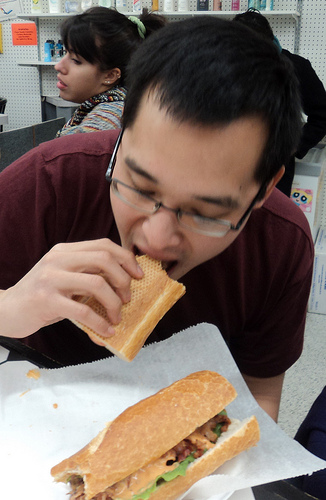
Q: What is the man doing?
A: Eating.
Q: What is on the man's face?
A: Glasses.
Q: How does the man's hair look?
A: Short.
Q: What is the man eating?
A: A sandwich.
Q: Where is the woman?
A: Behind the man.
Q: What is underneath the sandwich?
A: Wrapping paper.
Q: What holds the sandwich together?
A: Bread.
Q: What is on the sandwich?
A: Meat and spinach.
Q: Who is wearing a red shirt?
A: The man.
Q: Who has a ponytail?
A: The woman.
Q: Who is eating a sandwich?
A: The man.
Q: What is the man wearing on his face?
A: Glasses.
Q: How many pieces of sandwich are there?
A: 2.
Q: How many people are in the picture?
A: 3.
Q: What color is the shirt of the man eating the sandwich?
A: Maroon.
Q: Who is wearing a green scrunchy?
A: The woman.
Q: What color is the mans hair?
A: Black.